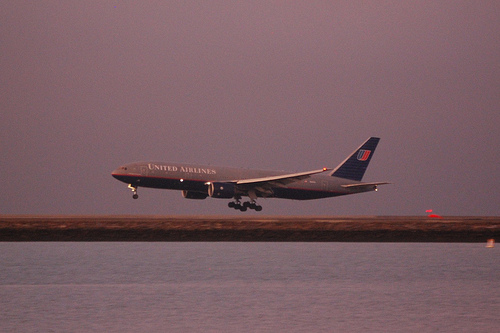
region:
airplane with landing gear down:
[107, 126, 392, 215]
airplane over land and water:
[105, 129, 396, 286]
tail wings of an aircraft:
[334, 128, 393, 199]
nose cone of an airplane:
[108, 156, 147, 202]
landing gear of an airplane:
[224, 193, 265, 214]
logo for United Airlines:
[353, 142, 377, 167]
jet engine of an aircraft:
[203, 181, 248, 200]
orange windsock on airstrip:
[418, 201, 446, 227]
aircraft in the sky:
[100, 126, 397, 213]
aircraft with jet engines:
[104, 124, 393, 215]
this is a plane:
[109, 128, 414, 203]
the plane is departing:
[109, 123, 410, 205]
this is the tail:
[345, 133, 390, 172]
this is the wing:
[264, 157, 331, 189]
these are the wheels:
[223, 200, 271, 214]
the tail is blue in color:
[338, 138, 381, 175]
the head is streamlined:
[109, 158, 140, 181]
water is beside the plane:
[231, 244, 353, 325]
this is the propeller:
[205, 180, 233, 197]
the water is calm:
[266, 245, 385, 323]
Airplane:
[82, 127, 412, 217]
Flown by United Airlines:
[91, 148, 449, 207]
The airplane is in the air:
[67, 133, 430, 209]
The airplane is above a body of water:
[71, 134, 421, 216]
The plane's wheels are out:
[105, 179, 283, 222]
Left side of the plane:
[83, 138, 425, 203]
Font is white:
[118, 148, 253, 180]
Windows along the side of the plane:
[138, 160, 295, 182]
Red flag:
[403, 198, 453, 221]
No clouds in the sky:
[12, 59, 479, 136]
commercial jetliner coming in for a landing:
[110, 136, 390, 211]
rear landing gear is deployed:
[228, 198, 262, 213]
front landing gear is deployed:
[131, 185, 137, 197]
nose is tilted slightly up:
[111, 161, 147, 185]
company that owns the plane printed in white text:
[147, 163, 215, 175]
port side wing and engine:
[205, 166, 331, 198]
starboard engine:
[180, 189, 207, 199]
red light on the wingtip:
[322, 166, 332, 171]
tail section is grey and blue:
[328, 136, 390, 197]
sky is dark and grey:
[0, 0, 499, 215]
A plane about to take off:
[108, 122, 391, 227]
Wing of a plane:
[230, 160, 335, 194]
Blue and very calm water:
[1, 235, 499, 331]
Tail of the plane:
[329, 131, 383, 181]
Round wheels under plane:
[224, 193, 265, 218]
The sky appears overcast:
[1, 0, 499, 215]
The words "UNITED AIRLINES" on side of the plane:
[145, 154, 222, 176]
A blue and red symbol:
[352, 142, 375, 167]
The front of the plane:
[107, 154, 147, 204]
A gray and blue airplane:
[109, 130, 395, 214]